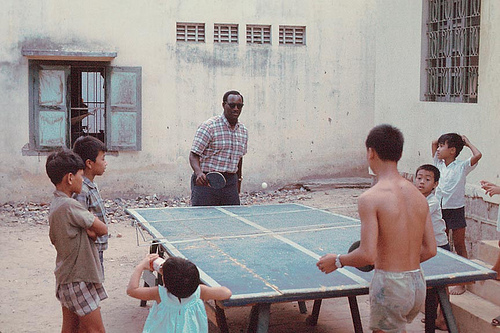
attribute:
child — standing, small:
[297, 121, 463, 332]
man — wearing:
[186, 90, 253, 207]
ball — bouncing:
[255, 178, 270, 191]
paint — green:
[234, 257, 288, 289]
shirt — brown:
[30, 190, 122, 280]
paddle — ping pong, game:
[205, 168, 229, 192]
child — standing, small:
[46, 149, 106, 331]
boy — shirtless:
[315, 123, 440, 331]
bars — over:
[429, 30, 474, 62]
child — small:
[412, 162, 451, 256]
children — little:
[38, 110, 490, 331]